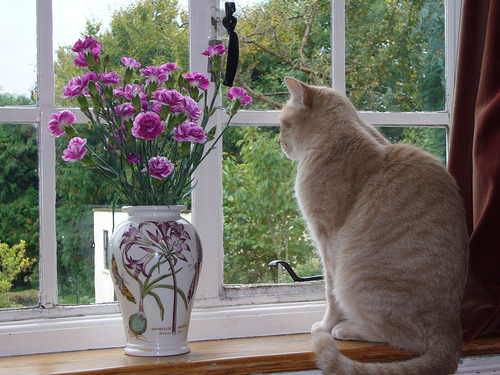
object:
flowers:
[106, 204, 202, 356]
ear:
[283, 76, 313, 109]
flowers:
[46, 35, 252, 181]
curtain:
[454, 0, 500, 346]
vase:
[107, 205, 202, 356]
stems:
[47, 34, 253, 206]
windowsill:
[0, 329, 500, 375]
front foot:
[310, 317, 340, 339]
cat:
[278, 76, 469, 375]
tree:
[218, 0, 446, 283]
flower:
[131, 111, 165, 141]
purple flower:
[142, 156, 175, 181]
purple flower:
[227, 86, 252, 105]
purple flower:
[172, 119, 208, 143]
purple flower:
[127, 110, 175, 180]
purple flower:
[61, 137, 88, 162]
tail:
[311, 329, 461, 374]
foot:
[331, 320, 370, 342]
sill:
[0, 330, 500, 375]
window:
[0, 0, 456, 361]